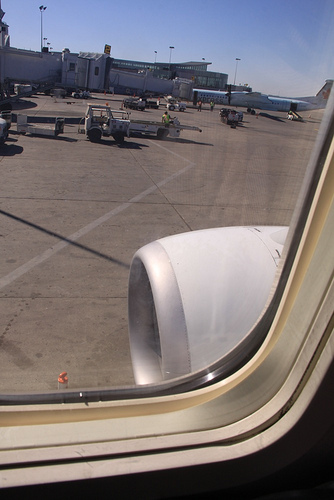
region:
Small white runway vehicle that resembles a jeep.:
[79, 102, 131, 143]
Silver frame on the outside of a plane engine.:
[126, 240, 190, 388]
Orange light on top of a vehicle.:
[104, 102, 111, 105]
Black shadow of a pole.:
[1, 209, 134, 271]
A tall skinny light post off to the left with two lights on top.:
[38, 4, 47, 52]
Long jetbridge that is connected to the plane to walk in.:
[104, 67, 194, 102]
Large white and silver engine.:
[125, 224, 291, 389]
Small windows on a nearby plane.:
[200, 92, 227, 100]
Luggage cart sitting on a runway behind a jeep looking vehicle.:
[16, 113, 64, 137]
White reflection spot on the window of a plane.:
[204, 369, 213, 381]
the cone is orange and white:
[52, 367, 86, 396]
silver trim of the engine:
[94, 232, 207, 398]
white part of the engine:
[162, 192, 319, 361]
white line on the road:
[2, 220, 76, 307]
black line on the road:
[2, 204, 148, 286]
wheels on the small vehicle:
[78, 126, 136, 148]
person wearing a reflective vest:
[150, 102, 189, 129]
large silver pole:
[31, 2, 67, 60]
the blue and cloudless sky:
[2, 3, 330, 97]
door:
[287, 99, 306, 119]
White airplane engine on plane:
[129, 227, 309, 387]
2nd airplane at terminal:
[184, 84, 333, 110]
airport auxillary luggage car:
[83, 102, 203, 145]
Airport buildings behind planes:
[2, 32, 228, 96]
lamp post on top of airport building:
[37, 2, 52, 55]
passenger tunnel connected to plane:
[108, 65, 178, 97]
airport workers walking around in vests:
[196, 99, 216, 110]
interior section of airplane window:
[70, 366, 314, 494]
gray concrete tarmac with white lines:
[63, 140, 281, 223]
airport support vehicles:
[125, 93, 186, 112]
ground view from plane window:
[35, 24, 305, 482]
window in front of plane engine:
[99, 215, 300, 388]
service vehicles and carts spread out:
[17, 76, 186, 157]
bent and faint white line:
[37, 122, 208, 276]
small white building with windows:
[48, 41, 112, 101]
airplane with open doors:
[181, 79, 311, 123]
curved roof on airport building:
[110, 47, 210, 67]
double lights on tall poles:
[33, 0, 244, 82]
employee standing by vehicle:
[144, 97, 192, 142]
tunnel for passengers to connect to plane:
[104, 68, 196, 103]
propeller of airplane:
[116, 208, 246, 388]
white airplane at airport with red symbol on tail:
[179, 74, 330, 113]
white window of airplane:
[25, 245, 303, 493]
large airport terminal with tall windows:
[29, 24, 253, 94]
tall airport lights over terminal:
[29, 0, 57, 58]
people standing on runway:
[192, 90, 221, 112]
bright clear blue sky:
[211, 4, 274, 45]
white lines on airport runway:
[23, 189, 127, 285]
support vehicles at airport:
[87, 89, 254, 141]